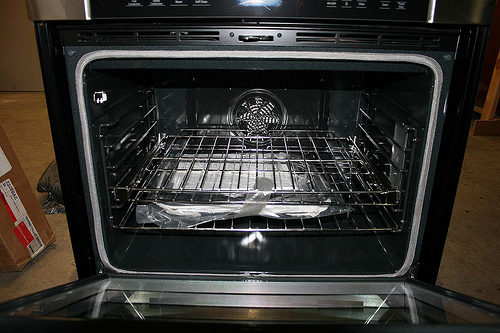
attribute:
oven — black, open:
[0, 1, 498, 331]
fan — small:
[236, 96, 279, 138]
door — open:
[0, 272, 499, 332]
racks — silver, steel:
[110, 128, 399, 233]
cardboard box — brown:
[0, 125, 56, 273]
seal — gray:
[75, 50, 442, 277]